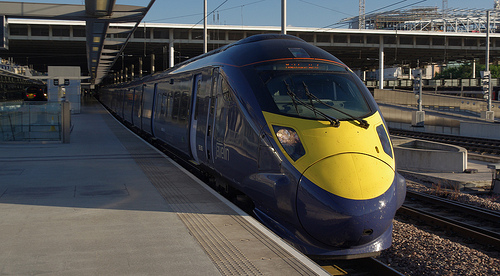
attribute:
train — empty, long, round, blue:
[106, 33, 409, 262]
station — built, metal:
[1, 2, 499, 274]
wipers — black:
[287, 85, 369, 129]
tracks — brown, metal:
[383, 126, 497, 274]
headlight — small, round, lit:
[279, 126, 306, 159]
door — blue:
[188, 71, 201, 166]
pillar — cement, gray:
[396, 130, 470, 173]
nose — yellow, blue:
[298, 142, 403, 241]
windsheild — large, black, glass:
[253, 58, 369, 122]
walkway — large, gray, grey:
[2, 91, 322, 276]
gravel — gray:
[390, 218, 498, 272]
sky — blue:
[78, 0, 499, 39]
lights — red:
[96, 88, 112, 104]